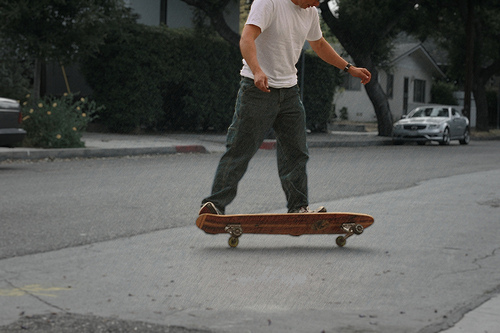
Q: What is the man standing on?
A: Skateboard.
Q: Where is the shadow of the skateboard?
A: Sidewalk.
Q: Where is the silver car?
A: Parked at the curb.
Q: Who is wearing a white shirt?
A: Skateboarder.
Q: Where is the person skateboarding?
A: Street.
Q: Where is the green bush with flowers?
A: On the sidewalk.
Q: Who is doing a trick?
A: The person on the skateboard.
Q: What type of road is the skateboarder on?
A: Paved.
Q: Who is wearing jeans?
A: Skateboarder.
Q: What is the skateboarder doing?
A: A trick.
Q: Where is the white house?
A: Behind the silver car.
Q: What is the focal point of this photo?
A: A man standing on a skateboard.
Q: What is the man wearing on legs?
A: A pair of blue jeans.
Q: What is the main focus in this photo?
A: A skateboarder in the street.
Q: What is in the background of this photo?
A: A row of green bushes.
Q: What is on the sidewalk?
A: A tree.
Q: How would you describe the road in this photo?
A: A gray paved road.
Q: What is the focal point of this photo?
A: A person skateboarding outside.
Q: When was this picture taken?
A: During the day.